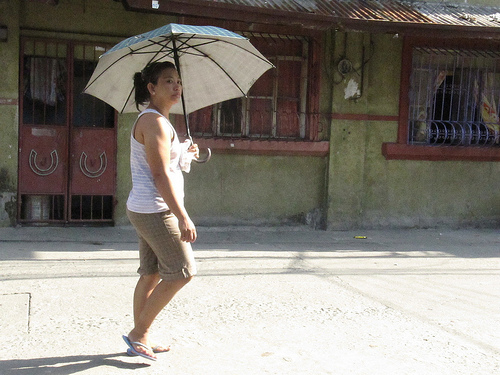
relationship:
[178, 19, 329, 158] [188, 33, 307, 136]
window covered in metal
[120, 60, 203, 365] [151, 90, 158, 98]
woman has earring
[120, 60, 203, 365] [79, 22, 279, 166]
woman holding umbrella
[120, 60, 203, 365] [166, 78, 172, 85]
woman has eye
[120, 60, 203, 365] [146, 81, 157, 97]
woman has ear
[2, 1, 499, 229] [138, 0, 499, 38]
building has roof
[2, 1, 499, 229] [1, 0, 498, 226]
building has wall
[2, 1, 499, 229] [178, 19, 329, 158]
building has window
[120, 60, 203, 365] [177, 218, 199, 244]
woman has right hand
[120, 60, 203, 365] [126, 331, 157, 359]
woman has right foot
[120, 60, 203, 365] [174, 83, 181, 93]
woman has nose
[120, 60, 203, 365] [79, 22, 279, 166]
woman under umbrella